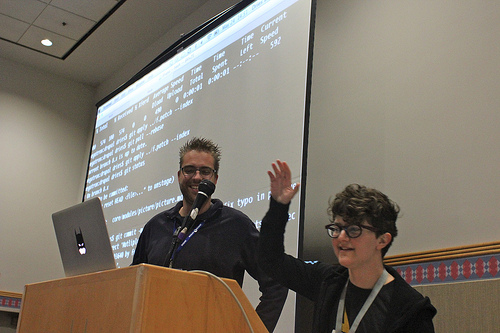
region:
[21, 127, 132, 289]
this is a silver MacBook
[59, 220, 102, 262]
a Batman decal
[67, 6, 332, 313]
this is a projector screen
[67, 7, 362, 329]
the screen is displaying a computer program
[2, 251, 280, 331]
this is a wooden podium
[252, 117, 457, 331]
his hand is raised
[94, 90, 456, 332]
they both are wearing glasses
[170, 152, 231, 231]
this is a black microphone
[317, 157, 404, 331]
he is wearing a grey lanyard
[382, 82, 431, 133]
Part of the wall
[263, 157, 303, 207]
The right hand of the person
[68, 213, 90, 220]
Part of the laptop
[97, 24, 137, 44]
Part of the ceiling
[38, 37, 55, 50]
A light on the ceiling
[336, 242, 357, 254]
The mouth of the person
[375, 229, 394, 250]
The left ear of the person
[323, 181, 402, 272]
The head of the person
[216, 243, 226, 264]
Part of the shirt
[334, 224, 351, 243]
The nose of the person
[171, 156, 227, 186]
the eyes of a man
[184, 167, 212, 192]
the nose of a man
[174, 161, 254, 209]
the mouth of a man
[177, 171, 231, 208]
the teeth of a man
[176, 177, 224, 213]
the lips of a man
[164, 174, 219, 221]
the chin of a man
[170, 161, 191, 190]
the ear of a man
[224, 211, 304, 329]
the arm of a man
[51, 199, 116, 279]
A lapotp on the podium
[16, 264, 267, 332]
A podium beneath the laptop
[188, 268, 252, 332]
A gray wire on top of the podium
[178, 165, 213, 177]
The man is wearing glasses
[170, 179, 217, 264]
A microphone connected to the podium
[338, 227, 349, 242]
The nose of the person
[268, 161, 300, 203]
The right hand of the person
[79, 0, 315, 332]
A display on the giant screen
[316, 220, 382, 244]
a black pair of glasses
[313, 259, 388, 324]
a light grey lanyard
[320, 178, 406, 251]
curly hair on a boy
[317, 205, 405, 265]
black glasses on boy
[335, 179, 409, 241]
brown hair on boy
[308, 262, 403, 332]
gray necklace on boy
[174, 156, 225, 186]
black glasses on man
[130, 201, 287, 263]
black shirt on man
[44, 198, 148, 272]
silver computer on stand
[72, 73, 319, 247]
large screen on wall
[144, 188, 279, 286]
black shirt on man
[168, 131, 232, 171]
spike hair on man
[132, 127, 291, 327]
Man wearing pair of glasses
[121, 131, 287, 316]
Man with spiked hair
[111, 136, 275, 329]
Man wearing black shirt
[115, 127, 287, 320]
Man standing behind podium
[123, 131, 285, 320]
Man standing behind laptop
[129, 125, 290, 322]
Man standing behind silver laptop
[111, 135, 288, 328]
Man standing behind computer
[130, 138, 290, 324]
Man standing behind silver computer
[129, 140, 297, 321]
Man standing behind wooden podium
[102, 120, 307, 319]
Man standing in front of screen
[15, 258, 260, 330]
brow wood podium in front of people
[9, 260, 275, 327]
brow wood podium in front of people